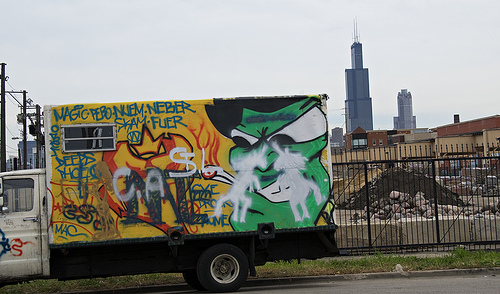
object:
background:
[1, 1, 498, 172]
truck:
[0, 94, 340, 292]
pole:
[36, 104, 42, 171]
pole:
[23, 91, 28, 170]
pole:
[0, 63, 7, 172]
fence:
[331, 149, 499, 255]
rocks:
[391, 190, 399, 199]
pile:
[363, 191, 460, 220]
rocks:
[415, 200, 425, 205]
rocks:
[422, 210, 434, 219]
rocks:
[445, 205, 451, 210]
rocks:
[377, 212, 387, 219]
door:
[0, 173, 44, 278]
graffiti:
[11, 237, 30, 255]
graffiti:
[0, 228, 10, 258]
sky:
[3, 0, 499, 159]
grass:
[2, 248, 498, 294]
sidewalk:
[286, 252, 498, 262]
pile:
[336, 167, 466, 209]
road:
[82, 266, 499, 293]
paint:
[0, 95, 335, 260]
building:
[344, 18, 374, 130]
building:
[392, 90, 416, 130]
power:
[29, 124, 38, 135]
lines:
[6, 81, 26, 93]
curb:
[82, 267, 498, 293]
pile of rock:
[357, 192, 497, 217]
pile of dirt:
[337, 165, 470, 209]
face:
[226, 96, 326, 176]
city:
[0, 1, 498, 294]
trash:
[396, 264, 410, 278]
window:
[61, 123, 115, 152]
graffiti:
[0, 95, 336, 257]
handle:
[23, 216, 38, 221]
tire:
[187, 243, 250, 292]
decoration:
[47, 94, 337, 247]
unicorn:
[271, 140, 326, 224]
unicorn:
[213, 141, 269, 225]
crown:
[130, 124, 164, 155]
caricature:
[228, 96, 332, 235]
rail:
[334, 157, 498, 163]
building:
[330, 115, 498, 175]